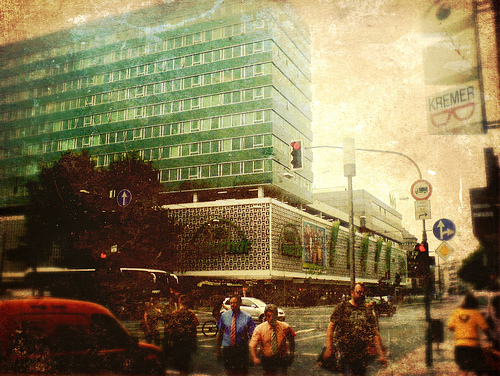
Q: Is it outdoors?
A: Yes, it is outdoors.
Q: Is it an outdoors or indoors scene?
A: It is outdoors.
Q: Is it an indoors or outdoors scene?
A: It is outdoors.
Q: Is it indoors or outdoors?
A: It is outdoors.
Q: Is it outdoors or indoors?
A: It is outdoors.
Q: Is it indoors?
A: No, it is outdoors.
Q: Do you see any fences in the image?
A: No, there are no fences.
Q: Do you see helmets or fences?
A: No, there are no fences or helmets.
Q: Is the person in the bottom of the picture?
A: Yes, the person is in the bottom of the image.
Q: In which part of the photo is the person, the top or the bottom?
A: The person is in the bottom of the image.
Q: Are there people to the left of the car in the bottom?
A: Yes, there is a person to the left of the car.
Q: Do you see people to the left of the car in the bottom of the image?
A: Yes, there is a person to the left of the car.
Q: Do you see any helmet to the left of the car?
A: No, there is a person to the left of the car.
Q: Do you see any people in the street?
A: Yes, there is a person in the street.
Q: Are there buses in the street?
A: No, there is a person in the street.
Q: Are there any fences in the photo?
A: No, there are no fences.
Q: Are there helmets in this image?
A: No, there are no helmets.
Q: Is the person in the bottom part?
A: Yes, the person is in the bottom of the image.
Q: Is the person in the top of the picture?
A: No, the person is in the bottom of the image.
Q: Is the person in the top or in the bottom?
A: The person is in the bottom of the image.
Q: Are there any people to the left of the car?
A: Yes, there is a person to the left of the car.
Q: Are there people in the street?
A: Yes, there is a person in the street.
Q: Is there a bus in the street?
A: No, there is a person in the street.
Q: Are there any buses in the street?
A: No, there is a person in the street.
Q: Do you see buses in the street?
A: No, there is a person in the street.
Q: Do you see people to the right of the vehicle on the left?
A: Yes, there is a person to the right of the minivan.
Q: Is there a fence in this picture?
A: No, there are no fences.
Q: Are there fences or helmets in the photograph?
A: No, there are no fences or helmets.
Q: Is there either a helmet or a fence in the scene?
A: No, there are no fences or helmets.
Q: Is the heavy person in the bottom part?
A: Yes, the person is in the bottom of the image.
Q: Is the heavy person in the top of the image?
A: No, the person is in the bottom of the image.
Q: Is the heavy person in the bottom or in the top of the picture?
A: The person is in the bottom of the image.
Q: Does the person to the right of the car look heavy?
A: Yes, the person is heavy.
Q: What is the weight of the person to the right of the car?
A: The person is heavy.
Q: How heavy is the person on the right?
A: The person is heavy.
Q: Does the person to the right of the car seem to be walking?
A: Yes, the person is walking.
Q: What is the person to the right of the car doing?
A: The person is walking.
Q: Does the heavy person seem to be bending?
A: No, the person is walking.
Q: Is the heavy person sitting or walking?
A: The person is walking.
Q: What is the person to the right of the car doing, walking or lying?
A: The person is walking.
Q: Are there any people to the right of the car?
A: Yes, there is a person to the right of the car.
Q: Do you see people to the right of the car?
A: Yes, there is a person to the right of the car.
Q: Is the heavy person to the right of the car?
A: Yes, the person is to the right of the car.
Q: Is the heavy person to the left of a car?
A: No, the person is to the right of a car.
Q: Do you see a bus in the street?
A: No, there is a person in the street.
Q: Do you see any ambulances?
A: No, there are no ambulances.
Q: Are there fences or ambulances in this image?
A: No, there are no ambulances or fences.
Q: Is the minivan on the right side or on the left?
A: The minivan is on the left of the image.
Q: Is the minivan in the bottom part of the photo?
A: Yes, the minivan is in the bottom of the image.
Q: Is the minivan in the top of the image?
A: No, the minivan is in the bottom of the image.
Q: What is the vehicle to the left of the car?
A: The vehicle is a minivan.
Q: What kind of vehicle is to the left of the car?
A: The vehicle is a minivan.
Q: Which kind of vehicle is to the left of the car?
A: The vehicle is a minivan.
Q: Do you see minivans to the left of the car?
A: Yes, there is a minivan to the left of the car.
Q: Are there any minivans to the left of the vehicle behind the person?
A: Yes, there is a minivan to the left of the car.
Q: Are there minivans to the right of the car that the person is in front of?
A: No, the minivan is to the left of the car.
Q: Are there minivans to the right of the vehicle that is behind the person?
A: No, the minivan is to the left of the car.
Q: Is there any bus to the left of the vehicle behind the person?
A: No, there is a minivan to the left of the car.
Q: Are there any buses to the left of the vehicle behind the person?
A: No, there is a minivan to the left of the car.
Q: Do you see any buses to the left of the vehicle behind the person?
A: No, there is a minivan to the left of the car.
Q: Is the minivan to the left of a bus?
A: No, the minivan is to the left of the car.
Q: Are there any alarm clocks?
A: No, there are no alarm clocks.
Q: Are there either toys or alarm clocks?
A: No, there are no alarm clocks or toys.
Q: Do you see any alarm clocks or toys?
A: No, there are no alarm clocks or toys.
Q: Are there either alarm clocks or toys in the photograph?
A: No, there are no alarm clocks or toys.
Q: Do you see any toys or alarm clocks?
A: No, there are no alarm clocks or toys.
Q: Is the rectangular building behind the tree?
A: Yes, the building is behind the tree.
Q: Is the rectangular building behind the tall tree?
A: Yes, the building is behind the tree.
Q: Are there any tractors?
A: No, there are no tractors.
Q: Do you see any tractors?
A: No, there are no tractors.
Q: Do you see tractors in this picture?
A: No, there are no tractors.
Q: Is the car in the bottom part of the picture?
A: Yes, the car is in the bottom of the image.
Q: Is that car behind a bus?
A: No, the car is behind a person.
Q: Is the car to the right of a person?
A: Yes, the car is to the right of a person.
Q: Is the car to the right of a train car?
A: No, the car is to the right of a person.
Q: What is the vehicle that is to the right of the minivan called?
A: The vehicle is a car.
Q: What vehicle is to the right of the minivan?
A: The vehicle is a car.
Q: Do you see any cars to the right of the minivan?
A: Yes, there is a car to the right of the minivan.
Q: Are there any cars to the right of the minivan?
A: Yes, there is a car to the right of the minivan.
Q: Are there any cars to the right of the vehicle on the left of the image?
A: Yes, there is a car to the right of the minivan.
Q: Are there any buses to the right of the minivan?
A: No, there is a car to the right of the minivan.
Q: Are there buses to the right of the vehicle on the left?
A: No, there is a car to the right of the minivan.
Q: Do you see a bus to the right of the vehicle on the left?
A: No, there is a car to the right of the minivan.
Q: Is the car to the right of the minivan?
A: Yes, the car is to the right of the minivan.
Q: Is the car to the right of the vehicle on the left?
A: Yes, the car is to the right of the minivan.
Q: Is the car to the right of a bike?
A: No, the car is to the right of the minivan.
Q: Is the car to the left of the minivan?
A: No, the car is to the right of the minivan.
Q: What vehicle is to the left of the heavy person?
A: The vehicle is a car.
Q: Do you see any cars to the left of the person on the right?
A: Yes, there is a car to the left of the person.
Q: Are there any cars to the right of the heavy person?
A: No, the car is to the left of the person.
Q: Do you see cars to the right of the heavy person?
A: No, the car is to the left of the person.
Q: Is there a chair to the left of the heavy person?
A: No, there is a car to the left of the person.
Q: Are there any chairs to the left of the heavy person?
A: No, there is a car to the left of the person.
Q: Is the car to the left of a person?
A: Yes, the car is to the left of a person.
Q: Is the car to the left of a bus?
A: No, the car is to the left of a person.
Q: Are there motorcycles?
A: No, there are no motorcycles.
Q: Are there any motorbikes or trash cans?
A: No, there are no motorbikes or trash cans.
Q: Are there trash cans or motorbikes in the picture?
A: No, there are no motorbikes or trash cans.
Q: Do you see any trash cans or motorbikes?
A: No, there are no motorbikes or trash cans.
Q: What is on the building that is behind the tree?
A: The sign is on the building.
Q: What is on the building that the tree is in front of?
A: The sign is on the building.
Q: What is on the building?
A: The sign is on the building.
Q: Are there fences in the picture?
A: No, there are no fences.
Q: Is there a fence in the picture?
A: No, there are no fences.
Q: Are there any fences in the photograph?
A: No, there are no fences.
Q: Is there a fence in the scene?
A: No, there are no fences.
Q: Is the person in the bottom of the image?
A: Yes, the person is in the bottom of the image.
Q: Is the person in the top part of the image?
A: No, the person is in the bottom of the image.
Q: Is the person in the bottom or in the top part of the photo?
A: The person is in the bottom of the image.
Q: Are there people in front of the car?
A: Yes, there is a person in front of the car.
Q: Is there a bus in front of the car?
A: No, there is a person in front of the car.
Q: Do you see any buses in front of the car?
A: No, there is a person in front of the car.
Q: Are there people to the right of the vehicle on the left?
A: Yes, there is a person to the right of the minivan.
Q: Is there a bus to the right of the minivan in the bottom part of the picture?
A: No, there is a person to the right of the minivan.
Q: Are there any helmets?
A: No, there are no helmets.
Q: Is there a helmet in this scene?
A: No, there are no helmets.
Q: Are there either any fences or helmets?
A: No, there are no helmets or fences.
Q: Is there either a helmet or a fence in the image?
A: No, there are no helmets or fences.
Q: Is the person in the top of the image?
A: No, the person is in the bottom of the image.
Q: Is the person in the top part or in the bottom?
A: The person is in the bottom of the image.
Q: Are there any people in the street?
A: Yes, there is a person in the street.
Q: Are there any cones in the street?
A: No, there is a person in the street.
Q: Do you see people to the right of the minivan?
A: Yes, there is a person to the right of the minivan.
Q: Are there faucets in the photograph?
A: No, there are no faucets.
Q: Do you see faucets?
A: No, there are no faucets.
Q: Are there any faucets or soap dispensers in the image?
A: No, there are no faucets or soap dispensers.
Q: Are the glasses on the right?
A: Yes, the glasses are on the right of the image.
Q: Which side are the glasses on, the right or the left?
A: The glasses are on the right of the image.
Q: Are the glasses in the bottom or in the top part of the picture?
A: The glasses are in the top of the image.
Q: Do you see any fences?
A: No, there are no fences.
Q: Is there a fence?
A: No, there are no fences.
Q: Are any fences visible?
A: No, there are no fences.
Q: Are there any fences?
A: No, there are no fences.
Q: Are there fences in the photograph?
A: No, there are no fences.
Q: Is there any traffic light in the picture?
A: Yes, there is a traffic light.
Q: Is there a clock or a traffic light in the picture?
A: Yes, there is a traffic light.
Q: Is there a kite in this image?
A: No, there are no kites.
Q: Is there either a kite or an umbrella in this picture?
A: No, there are no kites or umbrellas.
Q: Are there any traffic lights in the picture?
A: Yes, there is a traffic light.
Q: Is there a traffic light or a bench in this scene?
A: Yes, there is a traffic light.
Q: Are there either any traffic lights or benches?
A: Yes, there is a traffic light.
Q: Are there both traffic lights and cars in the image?
A: Yes, there are both a traffic light and a car.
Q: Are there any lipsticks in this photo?
A: No, there are no lipsticks.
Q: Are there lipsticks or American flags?
A: No, there are no lipsticks or American flags.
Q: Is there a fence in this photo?
A: No, there are no fences.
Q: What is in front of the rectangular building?
A: The tree is in front of the building.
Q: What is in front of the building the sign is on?
A: The tree is in front of the building.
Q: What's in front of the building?
A: The tree is in front of the building.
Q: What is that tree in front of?
A: The tree is in front of the building.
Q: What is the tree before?
A: The tree is in front of the building.